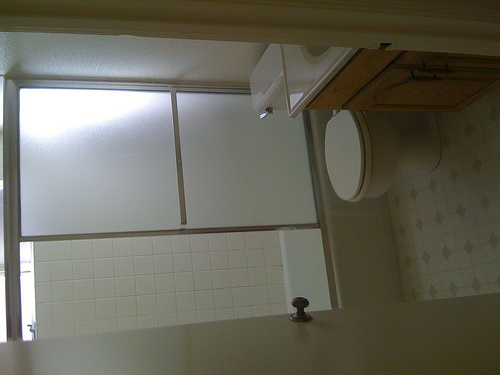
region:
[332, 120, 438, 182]
this is a toilet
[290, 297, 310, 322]
this is a handle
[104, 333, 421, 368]
this is a door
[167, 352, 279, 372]
the door is white in colour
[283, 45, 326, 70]
this is a sink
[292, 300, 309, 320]
the door handle is mettalic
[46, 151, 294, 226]
this is the window pane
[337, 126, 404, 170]
the toilet is white in color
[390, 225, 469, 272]
this is the floor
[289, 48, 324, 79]
the sink is white in colour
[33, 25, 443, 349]
this is a bathroom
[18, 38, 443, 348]
the bathroom is small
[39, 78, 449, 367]
this picture is sideways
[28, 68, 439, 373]
this photo is indoors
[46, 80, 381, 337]
the bathroom is lit up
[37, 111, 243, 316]
this is a shower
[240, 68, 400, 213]
this is a toilet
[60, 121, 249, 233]
this is a shower door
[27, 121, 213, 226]
the shower door is transparent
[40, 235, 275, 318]
the wall is tiled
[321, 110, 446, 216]
white bowl on toilet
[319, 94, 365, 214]
white lid on toilet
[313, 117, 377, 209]
toilet lid is lowered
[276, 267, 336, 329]
black handle on door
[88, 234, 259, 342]
white tile on wall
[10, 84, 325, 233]
metal frame on door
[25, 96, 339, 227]
white frosted shower door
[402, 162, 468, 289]
white and brown floor tile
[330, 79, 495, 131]
brown cabinets under sink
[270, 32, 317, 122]
white sink near toilet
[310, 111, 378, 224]
seat cover is closed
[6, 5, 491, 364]
Bathroom in a residential home.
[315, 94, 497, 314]
Decorative tiled flooring in a residential bathroom.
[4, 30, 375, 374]
Sliding shower door attached to a bathtub.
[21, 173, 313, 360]
White tiled porcelain wall inside of a bathroom.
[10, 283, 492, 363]
White door with a black door knob.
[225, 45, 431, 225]
White porcelain toilet with a stainless steel flush handle.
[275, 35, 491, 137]
Bathroom vanity with a porcelain sink top.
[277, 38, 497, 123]
Bathroom vanity with a wooden cabinet.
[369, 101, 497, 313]
Diamond pattern on bathroom tiled floor.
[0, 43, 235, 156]
Light coming from a bathroom window.